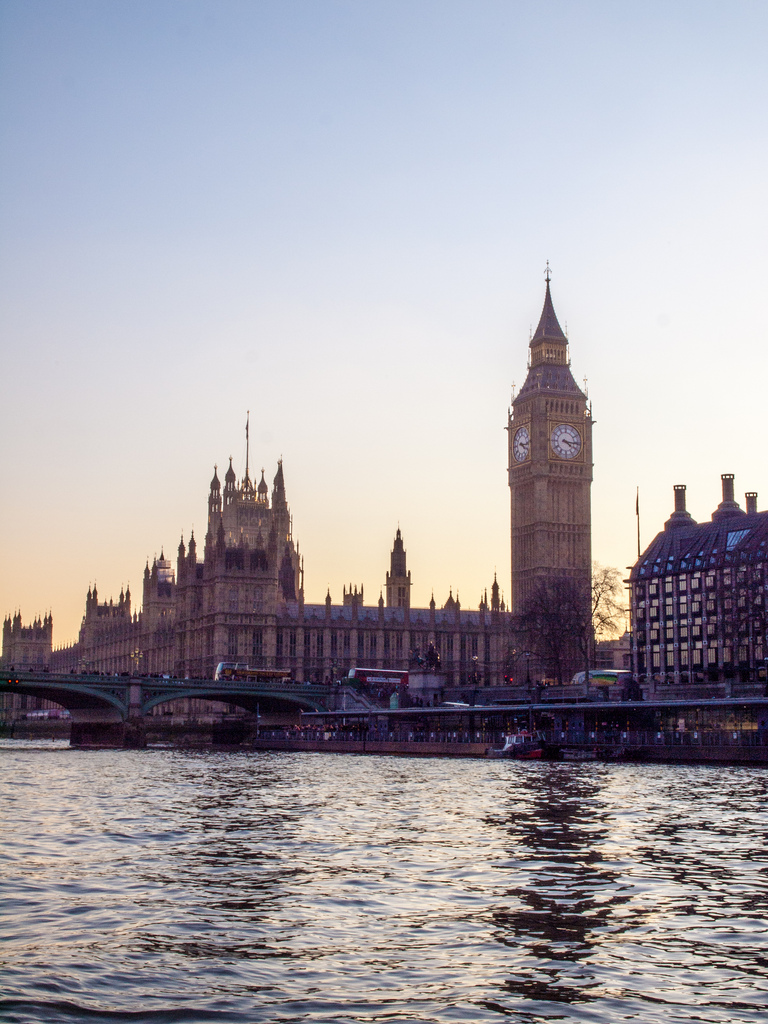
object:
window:
[692, 602, 700, 611]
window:
[666, 583, 673, 592]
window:
[637, 608, 644, 621]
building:
[623, 471, 767, 698]